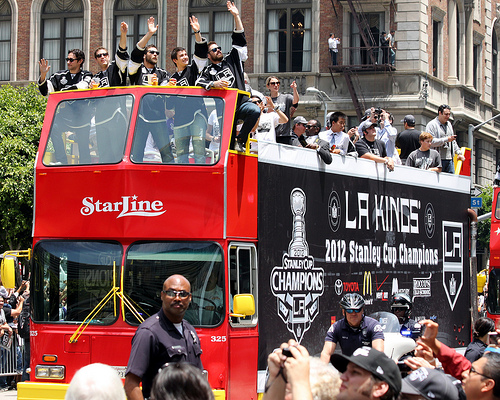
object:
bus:
[14, 86, 480, 400]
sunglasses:
[64, 57, 79, 62]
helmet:
[339, 292, 366, 310]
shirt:
[123, 308, 206, 385]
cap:
[328, 346, 402, 394]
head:
[170, 46, 189, 68]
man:
[168, 15, 208, 167]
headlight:
[34, 365, 66, 382]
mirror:
[233, 293, 256, 319]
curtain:
[66, 21, 83, 39]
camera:
[375, 106, 383, 115]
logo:
[78, 194, 167, 220]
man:
[123, 273, 209, 400]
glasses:
[162, 289, 193, 300]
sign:
[269, 188, 466, 344]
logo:
[362, 270, 374, 296]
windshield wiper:
[65, 260, 118, 344]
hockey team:
[29, 0, 261, 165]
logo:
[268, 186, 326, 342]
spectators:
[416, 319, 500, 399]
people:
[300, 118, 331, 165]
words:
[344, 190, 358, 232]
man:
[395, 115, 422, 167]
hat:
[400, 114, 415, 122]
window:
[128, 92, 226, 169]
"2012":
[324, 238, 347, 263]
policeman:
[123, 274, 205, 399]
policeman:
[319, 291, 383, 368]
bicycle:
[325, 347, 395, 362]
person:
[263, 338, 403, 400]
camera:
[280, 347, 293, 359]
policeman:
[389, 293, 420, 333]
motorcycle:
[367, 310, 439, 361]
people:
[379, 31, 390, 65]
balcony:
[328, 42, 396, 72]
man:
[37, 49, 92, 164]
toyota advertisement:
[333, 278, 360, 295]